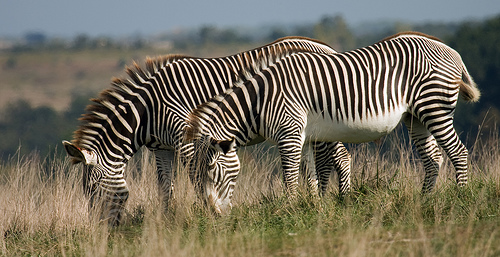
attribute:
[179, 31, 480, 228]
zebra — grazing, eating, flapping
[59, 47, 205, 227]
zebra — arched, eating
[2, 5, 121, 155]
landscape — blurred